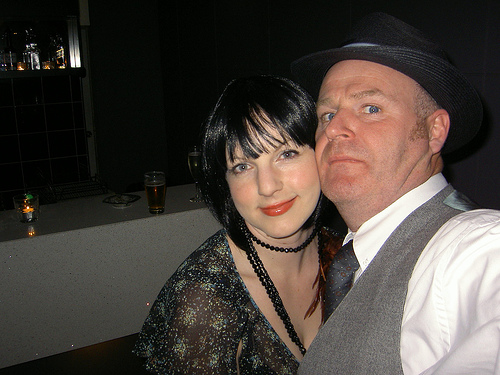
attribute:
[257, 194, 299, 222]
lips — polished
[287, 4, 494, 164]
hat — black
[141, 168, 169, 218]
glass — full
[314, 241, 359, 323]
tie — grey, tied, speckled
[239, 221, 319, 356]
necklace — black, beaded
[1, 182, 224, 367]
bar — gray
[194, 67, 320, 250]
hair — black, shiny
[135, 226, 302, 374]
shirt — black, printed, blue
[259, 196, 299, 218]
lips — red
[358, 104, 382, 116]
eye — blue, clear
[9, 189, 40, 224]
candle — burning, glowing, lit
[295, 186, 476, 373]
vest — gray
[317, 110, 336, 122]
eye — blue, clear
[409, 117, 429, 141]
sideburn — short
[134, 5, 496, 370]
couple — posing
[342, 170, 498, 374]
shirt — white